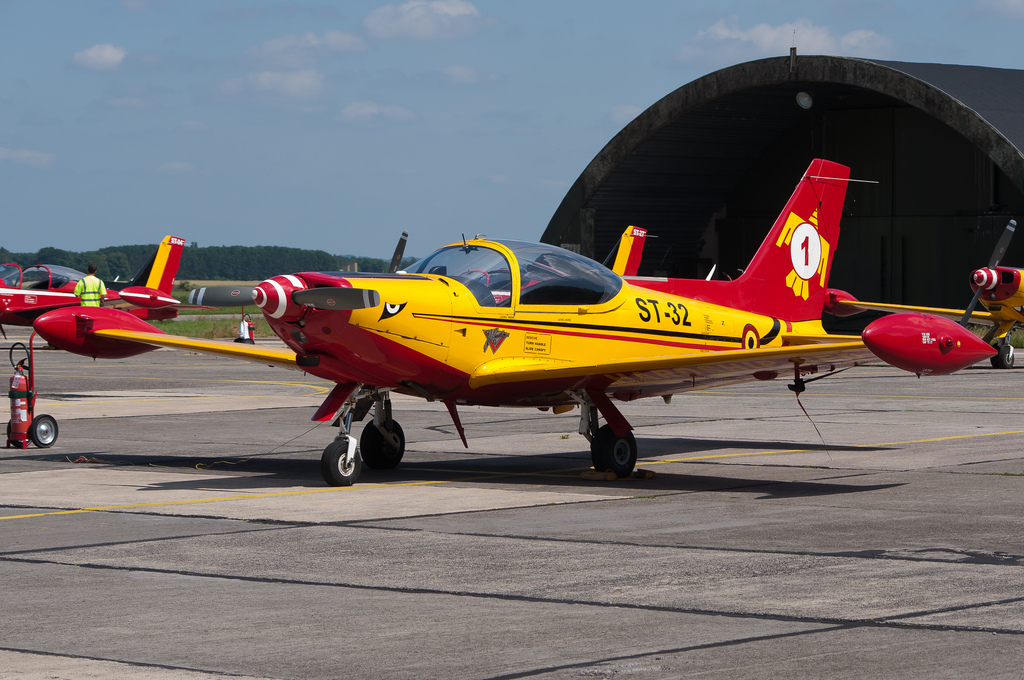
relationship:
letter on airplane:
[647, 293, 669, 322] [148, 152, 1014, 453]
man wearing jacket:
[71, 261, 111, 309] [76, 274, 109, 300]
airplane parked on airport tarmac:
[3, 230, 213, 324] [0, 328, 1021, 674]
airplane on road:
[148, 152, 1014, 453] [375, 501, 1002, 673]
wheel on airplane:
[320, 435, 374, 483] [6, 148, 981, 498]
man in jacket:
[65, 253, 98, 323] [71, 273, 111, 306]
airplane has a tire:
[148, 152, 1014, 453] [531, 398, 676, 498]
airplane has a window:
[148, 152, 1014, 453] [414, 217, 622, 324]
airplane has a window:
[148, 152, 1014, 453] [427, 219, 611, 345]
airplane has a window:
[148, 152, 1014, 453] [419, 223, 649, 345]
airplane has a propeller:
[148, 152, 1014, 453] [132, 236, 374, 334]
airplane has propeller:
[148, 152, 1014, 453] [164, 270, 281, 331]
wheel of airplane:
[311, 420, 385, 490] [148, 152, 1014, 453]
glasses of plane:
[410, 206, 625, 341] [47, 102, 1000, 602]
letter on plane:
[621, 273, 669, 330] [163, 141, 926, 498]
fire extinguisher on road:
[12, 325, 51, 447] [375, 501, 1002, 673]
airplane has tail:
[148, 152, 1015, 453] [692, 147, 865, 329]